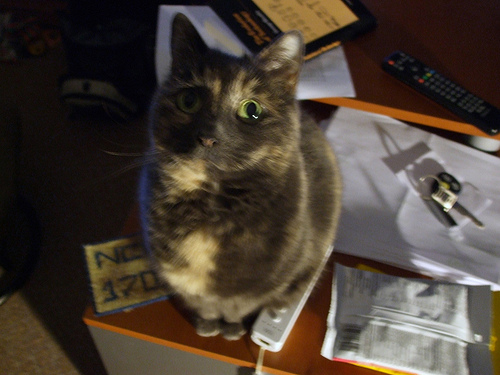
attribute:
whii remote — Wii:
[244, 230, 341, 355]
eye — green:
[174, 88, 206, 117]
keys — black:
[410, 168, 486, 237]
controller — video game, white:
[249, 240, 333, 353]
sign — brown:
[83, 235, 177, 312]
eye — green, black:
[237, 93, 262, 121]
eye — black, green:
[177, 85, 202, 113]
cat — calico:
[128, 10, 353, 350]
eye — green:
[239, 97, 261, 121]